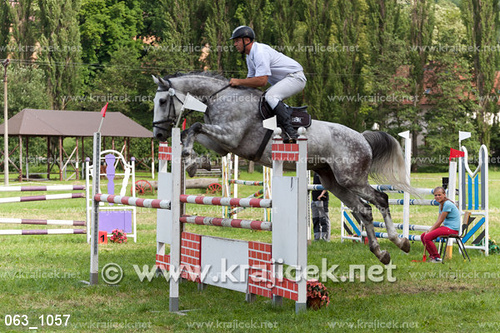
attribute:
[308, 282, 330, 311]
flowers — pink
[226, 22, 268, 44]
helmet —  black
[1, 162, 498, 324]
grass — green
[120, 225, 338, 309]
brick —  red and white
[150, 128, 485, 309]
poles —  wooden,  white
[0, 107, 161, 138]
shade —  covering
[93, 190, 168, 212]
bars —  red and white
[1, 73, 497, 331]
race field — for race, for  Horse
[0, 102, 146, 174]
awning —  brown 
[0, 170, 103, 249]
barrier — purple, white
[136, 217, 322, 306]
bricks —  bricks painted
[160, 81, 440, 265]
horse — white, gray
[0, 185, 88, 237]
hurdle —  purple and white,  for horse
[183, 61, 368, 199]
horse — race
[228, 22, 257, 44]
helmet — black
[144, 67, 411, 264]
horse — gray, black,  dapple ,  grey,  leaping